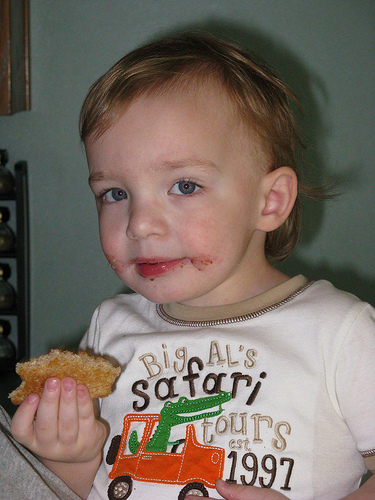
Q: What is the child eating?
A: Toast.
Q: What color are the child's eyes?
A: Blue.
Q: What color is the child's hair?
A: Red.